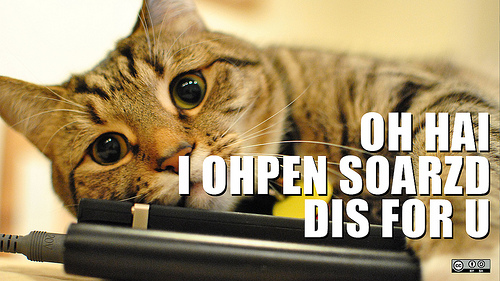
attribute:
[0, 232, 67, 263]
charger — here